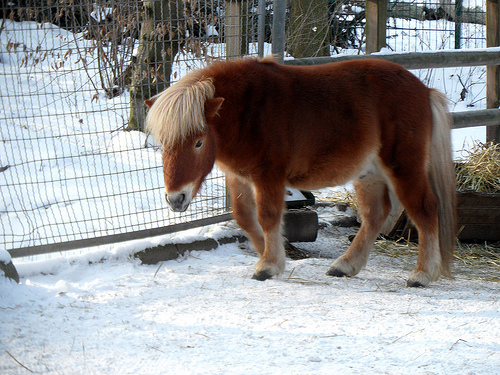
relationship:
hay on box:
[452, 139, 499, 191] [373, 176, 498, 240]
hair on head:
[138, 74, 211, 146] [146, 92, 226, 214]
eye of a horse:
[192, 136, 208, 150] [142, 58, 466, 290]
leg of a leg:
[391, 162, 441, 287] [331, 182, 386, 277]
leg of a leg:
[391, 162, 441, 287] [253, 177, 286, 280]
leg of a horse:
[391, 162, 441, 287] [142, 58, 466, 290]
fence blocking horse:
[8, 0, 488, 245] [142, 58, 466, 290]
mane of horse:
[139, 77, 215, 139] [142, 55, 467, 290]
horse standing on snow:
[142, 55, 467, 290] [0, 237, 498, 373]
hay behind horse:
[452, 139, 500, 192] [142, 55, 467, 290]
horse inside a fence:
[142, 58, 466, 290] [8, 0, 488, 245]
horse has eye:
[142, 55, 467, 290] [183, 121, 210, 154]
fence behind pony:
[8, 0, 488, 245] [152, 64, 485, 296]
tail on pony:
[415, 93, 467, 269] [132, 67, 403, 260]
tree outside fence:
[91, 1, 201, 128] [3, 6, 496, 222]